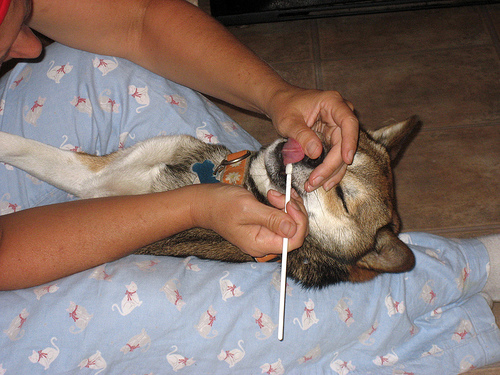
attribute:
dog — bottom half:
[3, 75, 438, 299]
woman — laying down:
[0, 2, 362, 301]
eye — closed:
[321, 180, 359, 222]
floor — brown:
[211, 13, 496, 242]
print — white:
[69, 86, 126, 134]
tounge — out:
[279, 140, 305, 169]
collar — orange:
[220, 147, 253, 203]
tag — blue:
[189, 154, 218, 191]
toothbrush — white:
[277, 158, 289, 344]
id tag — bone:
[192, 153, 226, 195]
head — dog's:
[251, 92, 433, 321]